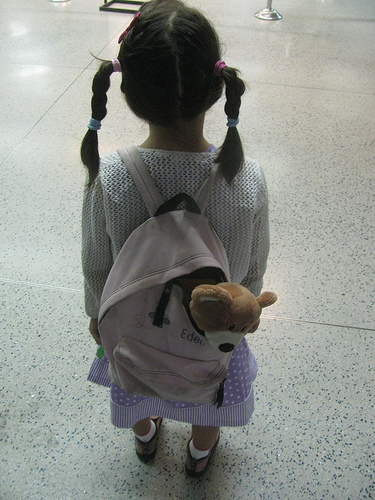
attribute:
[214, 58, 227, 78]
hair tie — darker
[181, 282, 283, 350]
teddy bear — brown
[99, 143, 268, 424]
backpack — grey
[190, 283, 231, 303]
ear — larger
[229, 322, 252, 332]
eyes — black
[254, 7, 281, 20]
base — round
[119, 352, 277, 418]
cloth — violet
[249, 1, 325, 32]
stand — silver, shiny, metal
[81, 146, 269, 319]
sweater — whitish, grey, long sleeved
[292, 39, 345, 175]
floor — tiled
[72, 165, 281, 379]
sweater — white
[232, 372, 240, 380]
dot — white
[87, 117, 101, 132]
band — green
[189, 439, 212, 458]
sock — white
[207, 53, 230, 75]
hair band — pink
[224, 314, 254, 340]
eyes — black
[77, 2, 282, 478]
girl — dark haired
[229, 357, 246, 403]
spots — white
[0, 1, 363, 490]
floor — clear, shiny, reflective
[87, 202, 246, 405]
bag — open